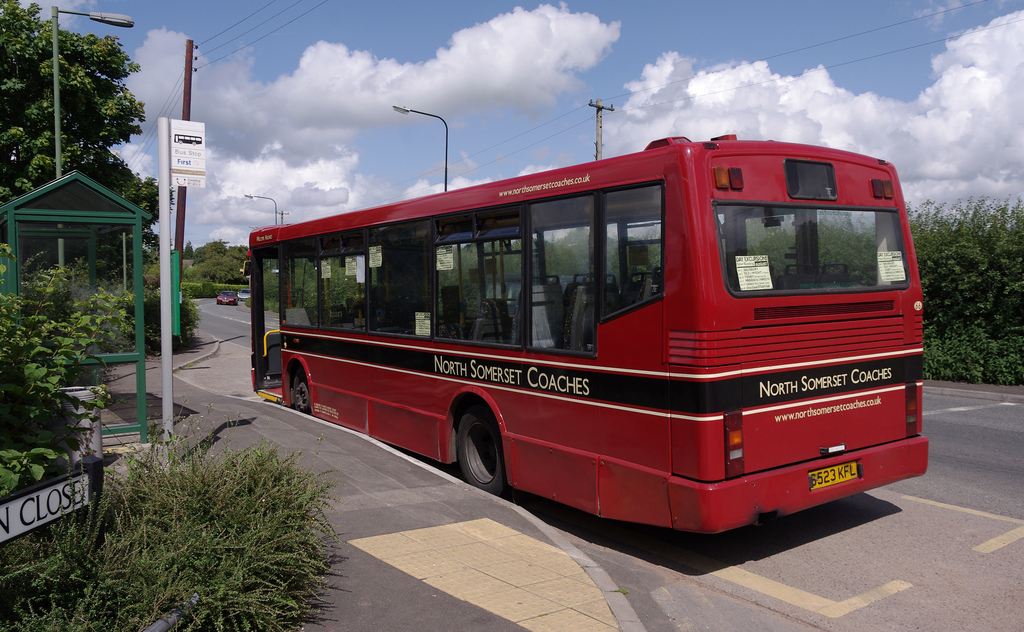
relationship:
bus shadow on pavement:
[510, 489, 897, 584] [90, 294, 1022, 629]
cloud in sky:
[606, 14, 1021, 212] [2, 1, 1022, 256]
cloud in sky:
[141, 138, 370, 225] [2, 1, 1022, 256]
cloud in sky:
[137, 1, 627, 147] [2, 1, 1022, 256]